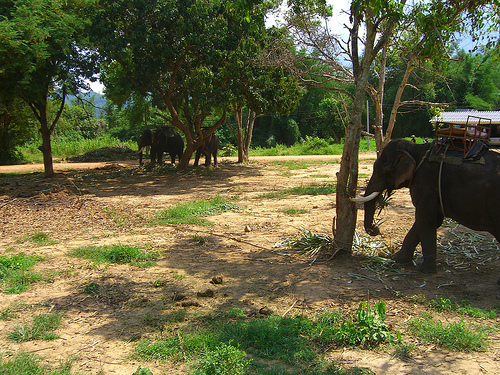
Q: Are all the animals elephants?
A: Yes, all the animals are elephants.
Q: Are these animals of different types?
A: No, all the animals are elephants.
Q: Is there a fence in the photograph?
A: No, there are no fences.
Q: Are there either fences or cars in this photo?
A: No, there are no fences or cars.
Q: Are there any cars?
A: No, there are no cars.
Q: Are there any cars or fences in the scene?
A: No, there are no cars or fences.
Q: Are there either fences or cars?
A: No, there are no cars or fences.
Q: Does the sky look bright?
A: Yes, the sky is bright.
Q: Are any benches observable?
A: Yes, there is a bench.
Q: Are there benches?
A: Yes, there is a bench.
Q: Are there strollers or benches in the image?
A: Yes, there is a bench.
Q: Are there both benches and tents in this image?
A: No, there is a bench but no tents.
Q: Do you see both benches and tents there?
A: No, there is a bench but no tents.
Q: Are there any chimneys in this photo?
A: No, there are no chimneys.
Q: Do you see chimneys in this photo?
A: No, there are no chimneys.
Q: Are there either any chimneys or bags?
A: No, there are no chimneys or bags.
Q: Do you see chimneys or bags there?
A: No, there are no chimneys or bags.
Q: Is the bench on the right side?
A: Yes, the bench is on the right of the image.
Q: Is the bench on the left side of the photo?
A: No, the bench is on the right of the image.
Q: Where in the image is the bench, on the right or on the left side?
A: The bench is on the right of the image.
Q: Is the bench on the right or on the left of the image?
A: The bench is on the right of the image.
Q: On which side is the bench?
A: The bench is on the right of the image.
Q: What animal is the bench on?
A: The bench is on the elephant.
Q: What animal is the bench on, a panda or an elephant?
A: The bench is on an elephant.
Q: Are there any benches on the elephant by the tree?
A: Yes, there is a bench on the elephant.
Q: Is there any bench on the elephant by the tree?
A: Yes, there is a bench on the elephant.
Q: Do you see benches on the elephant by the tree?
A: Yes, there is a bench on the elephant.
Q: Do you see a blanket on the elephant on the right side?
A: No, there is a bench on the elephant.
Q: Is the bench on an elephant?
A: Yes, the bench is on an elephant.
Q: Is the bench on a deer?
A: No, the bench is on an elephant.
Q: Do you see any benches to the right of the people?
A: Yes, there is a bench to the right of the people.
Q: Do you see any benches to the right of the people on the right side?
A: Yes, there is a bench to the right of the people.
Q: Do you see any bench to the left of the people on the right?
A: No, the bench is to the right of the people.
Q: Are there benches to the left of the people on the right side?
A: No, the bench is to the right of the people.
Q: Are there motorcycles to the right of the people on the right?
A: No, there is a bench to the right of the people.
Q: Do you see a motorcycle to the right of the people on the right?
A: No, there is a bench to the right of the people.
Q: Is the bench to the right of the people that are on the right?
A: Yes, the bench is to the right of the people.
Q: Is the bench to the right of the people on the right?
A: Yes, the bench is to the right of the people.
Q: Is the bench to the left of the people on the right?
A: No, the bench is to the right of the people.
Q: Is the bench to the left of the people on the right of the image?
A: No, the bench is to the right of the people.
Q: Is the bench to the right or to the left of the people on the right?
A: The bench is to the right of the people.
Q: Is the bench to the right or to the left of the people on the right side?
A: The bench is to the right of the people.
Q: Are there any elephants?
A: Yes, there are elephants.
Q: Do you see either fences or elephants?
A: Yes, there are elephants.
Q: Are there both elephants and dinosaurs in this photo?
A: No, there are elephants but no dinosaurs.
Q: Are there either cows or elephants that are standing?
A: Yes, the elephants are standing.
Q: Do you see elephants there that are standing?
A: Yes, there are elephants that are standing.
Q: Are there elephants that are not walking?
A: Yes, there are elephants that are standing.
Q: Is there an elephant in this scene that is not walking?
A: Yes, there are elephants that are standing.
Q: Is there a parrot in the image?
A: No, there are no parrots.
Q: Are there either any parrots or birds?
A: No, there are no parrots or birds.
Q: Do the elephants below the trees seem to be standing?
A: Yes, the elephants are standing.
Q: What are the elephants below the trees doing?
A: The elephants are standing.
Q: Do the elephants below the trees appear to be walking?
A: No, the elephants are standing.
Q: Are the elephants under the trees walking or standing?
A: The elephants are standing.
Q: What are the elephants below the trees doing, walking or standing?
A: The elephants are standing.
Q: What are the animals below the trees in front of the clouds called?
A: The animals are elephants.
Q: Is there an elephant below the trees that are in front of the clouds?
A: Yes, there are elephants below the trees.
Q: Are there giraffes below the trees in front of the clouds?
A: No, there are elephants below the trees.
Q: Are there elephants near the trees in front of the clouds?
A: Yes, there are elephants near the trees.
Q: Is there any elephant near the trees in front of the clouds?
A: Yes, there are elephants near the trees.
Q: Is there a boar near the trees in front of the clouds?
A: No, there are elephants near the trees.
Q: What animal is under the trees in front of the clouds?
A: The elephants are under the trees.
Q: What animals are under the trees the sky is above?
A: The animals are elephants.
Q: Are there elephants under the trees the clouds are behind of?
A: Yes, there are elephants under the trees.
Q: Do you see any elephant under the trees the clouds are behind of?
A: Yes, there are elephants under the trees.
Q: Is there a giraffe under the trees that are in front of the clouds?
A: No, there are elephants under the trees.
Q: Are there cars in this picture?
A: No, there are no cars.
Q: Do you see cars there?
A: No, there are no cars.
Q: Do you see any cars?
A: No, there are no cars.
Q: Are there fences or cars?
A: No, there are no cars or fences.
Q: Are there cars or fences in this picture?
A: No, there are no cars or fences.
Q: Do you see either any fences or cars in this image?
A: No, there are no cars or fences.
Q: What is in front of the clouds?
A: The trees are in front of the clouds.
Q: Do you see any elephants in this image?
A: Yes, there is an elephant.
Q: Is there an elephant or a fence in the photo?
A: Yes, there is an elephant.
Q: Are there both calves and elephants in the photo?
A: No, there is an elephant but no calves.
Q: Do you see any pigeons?
A: No, there are no pigeons.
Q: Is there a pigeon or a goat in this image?
A: No, there are no pigeons or goats.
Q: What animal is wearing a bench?
A: The elephant is wearing a bench.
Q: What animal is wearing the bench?
A: The elephant is wearing a bench.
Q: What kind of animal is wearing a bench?
A: The animal is an elephant.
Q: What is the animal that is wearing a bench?
A: The animal is an elephant.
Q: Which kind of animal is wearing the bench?
A: The animal is an elephant.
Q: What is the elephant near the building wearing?
A: The elephant is wearing a bench.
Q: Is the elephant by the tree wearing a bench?
A: Yes, the elephant is wearing a bench.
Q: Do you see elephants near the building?
A: Yes, there is an elephant near the building.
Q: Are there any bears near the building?
A: No, there is an elephant near the building.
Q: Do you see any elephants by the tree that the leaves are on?
A: Yes, there is an elephant by the tree.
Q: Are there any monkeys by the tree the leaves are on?
A: No, there is an elephant by the tree.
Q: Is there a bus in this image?
A: No, there are no buses.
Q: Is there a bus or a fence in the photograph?
A: No, there are no buses or fences.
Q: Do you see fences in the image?
A: No, there are no fences.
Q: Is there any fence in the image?
A: No, there are no fences.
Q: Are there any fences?
A: No, there are no fences.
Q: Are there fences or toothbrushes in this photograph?
A: No, there are no fences or toothbrushes.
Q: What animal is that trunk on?
A: The trunk is on the elephant.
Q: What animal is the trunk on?
A: The trunk is on the elephant.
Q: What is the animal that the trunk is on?
A: The animal is an elephant.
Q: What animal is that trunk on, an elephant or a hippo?
A: The trunk is on an elephant.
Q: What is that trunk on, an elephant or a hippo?
A: The trunk is on an elephant.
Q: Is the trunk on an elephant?
A: Yes, the trunk is on an elephant.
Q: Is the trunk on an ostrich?
A: No, the trunk is on an elephant.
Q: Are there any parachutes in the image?
A: No, there are no parachutes.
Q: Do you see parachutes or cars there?
A: No, there are no parachutes or cars.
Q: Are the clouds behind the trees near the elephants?
A: Yes, the clouds are behind the trees.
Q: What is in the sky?
A: The clouds are in the sky.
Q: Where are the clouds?
A: The clouds are in the sky.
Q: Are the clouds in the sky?
A: Yes, the clouds are in the sky.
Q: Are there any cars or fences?
A: No, there are no cars or fences.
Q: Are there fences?
A: No, there are no fences.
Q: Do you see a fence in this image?
A: No, there are no fences.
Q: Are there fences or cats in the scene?
A: No, there are no fences or cats.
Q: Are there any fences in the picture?
A: No, there are no fences.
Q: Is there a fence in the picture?
A: No, there are no fences.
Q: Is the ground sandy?
A: Yes, the ground is sandy.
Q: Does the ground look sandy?
A: Yes, the ground is sandy.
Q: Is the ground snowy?
A: No, the ground is sandy.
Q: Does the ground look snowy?
A: No, the ground is sandy.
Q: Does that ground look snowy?
A: No, the ground is sandy.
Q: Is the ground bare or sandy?
A: The ground is sandy.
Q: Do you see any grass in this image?
A: Yes, there is grass.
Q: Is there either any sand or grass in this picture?
A: Yes, there is grass.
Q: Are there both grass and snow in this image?
A: No, there is grass but no snow.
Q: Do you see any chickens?
A: No, there are no chickens.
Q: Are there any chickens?
A: No, there are no chickens.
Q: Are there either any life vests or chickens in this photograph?
A: No, there are no chickens or life vests.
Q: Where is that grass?
A: The grass is on the ground.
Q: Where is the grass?
A: The grass is on the ground.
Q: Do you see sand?
A: Yes, there is sand.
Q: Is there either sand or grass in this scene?
A: Yes, there is sand.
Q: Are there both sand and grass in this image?
A: Yes, there are both sand and grass.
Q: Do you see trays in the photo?
A: No, there are no trays.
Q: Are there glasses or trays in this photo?
A: No, there are no trays or glasses.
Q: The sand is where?
A: The sand is on the grass.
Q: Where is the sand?
A: The sand is on the grass.